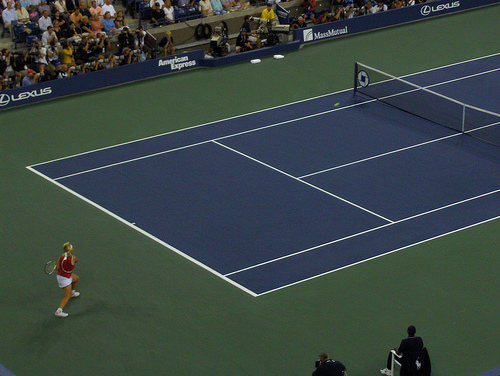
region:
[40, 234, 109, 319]
this is a player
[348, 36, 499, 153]
this is a net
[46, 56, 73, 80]
a person watching a match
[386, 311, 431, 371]
a person watching a match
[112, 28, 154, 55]
a person watching a match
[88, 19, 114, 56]
a person watching a match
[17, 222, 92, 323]
player is playing tennis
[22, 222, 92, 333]
player is playing tennis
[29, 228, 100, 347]
player is playing tennis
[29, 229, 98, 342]
player is playing tennis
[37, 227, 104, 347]
player is playing tennis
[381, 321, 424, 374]
man is sitting on a chair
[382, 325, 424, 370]
man is sitting on a chair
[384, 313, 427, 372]
man is sitting on a chair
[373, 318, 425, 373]
man is sitting on a chair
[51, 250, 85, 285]
woman wearing red shirt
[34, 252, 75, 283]
this is a tennis racket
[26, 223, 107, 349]
woman holding a tennis racket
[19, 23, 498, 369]
a large tennis court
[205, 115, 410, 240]
white line on court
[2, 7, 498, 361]
green trim around court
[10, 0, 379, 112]
spectators watching tennis match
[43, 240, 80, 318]
the lady playing tennis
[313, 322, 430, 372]
the people sitting on the court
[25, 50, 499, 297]
the blue on the tennis court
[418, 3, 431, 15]
the lexus logo on the short wall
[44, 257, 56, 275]
the net of the racket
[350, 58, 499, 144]
the net on the court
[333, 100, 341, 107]
the tennis ball in motion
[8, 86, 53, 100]
the word LEXUS on the short wall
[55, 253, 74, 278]
the red top on the woman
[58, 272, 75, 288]
the white skirt on the woman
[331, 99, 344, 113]
The tennis ball is in the air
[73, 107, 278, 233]
The court is green and blue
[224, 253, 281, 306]
Lines painted on a court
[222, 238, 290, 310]
Lines painted on a tennis court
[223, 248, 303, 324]
White lines painted on a court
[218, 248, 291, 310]
White lines painted on a tennis court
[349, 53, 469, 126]
Net on a court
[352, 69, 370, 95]
white and blue logo on net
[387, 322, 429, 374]
referee watching match from white stand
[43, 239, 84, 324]
woman in red playing tennis